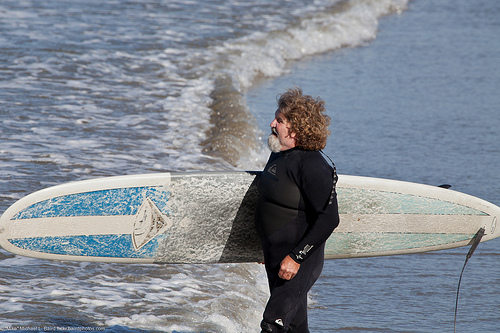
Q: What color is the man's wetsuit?
A: Black.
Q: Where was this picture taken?
A: The ocean.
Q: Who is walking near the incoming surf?
A: A pudgy person in a wetsuit.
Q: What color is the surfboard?
A: White and blue.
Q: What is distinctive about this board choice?
A: It appears bigger and longer than the man using it.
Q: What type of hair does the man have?
A: Thick and curly.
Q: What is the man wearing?
A: A black wetsuit.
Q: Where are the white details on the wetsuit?
A: On the arm of the wetsuit.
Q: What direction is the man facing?
A: Left.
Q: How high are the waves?
A: Shallow, presently.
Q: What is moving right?
A: The incoming waves and the man's hair with the breeze.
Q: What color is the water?
A: Blue.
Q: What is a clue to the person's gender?
A: Beard.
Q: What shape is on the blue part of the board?
A: Diamond.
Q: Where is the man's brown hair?
A: On head.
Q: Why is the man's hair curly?
A: Natural hair.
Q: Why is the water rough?
A: Incoming tide.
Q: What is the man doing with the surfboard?
A: Carrying it.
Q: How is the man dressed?
A: Black wetsuit.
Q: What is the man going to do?
A: Surf.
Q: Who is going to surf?
A: The man.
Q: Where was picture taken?
A: On the beach.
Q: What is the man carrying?
A: A surfboard.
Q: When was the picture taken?
A: Daytime.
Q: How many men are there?
A: One.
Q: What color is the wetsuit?
A: Black.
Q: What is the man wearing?
A: A wetsuit.